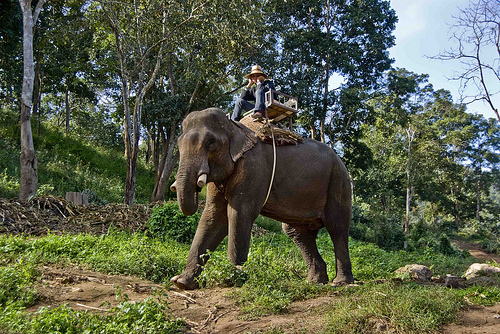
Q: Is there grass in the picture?
A: Yes, there is grass.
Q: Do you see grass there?
A: Yes, there is grass.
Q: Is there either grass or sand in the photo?
A: Yes, there is grass.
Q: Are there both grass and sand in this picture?
A: No, there is grass but no sand.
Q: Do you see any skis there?
A: No, there are no skis.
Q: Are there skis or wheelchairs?
A: No, there are no skis or wheelchairs.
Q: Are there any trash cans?
A: No, there are no trash cans.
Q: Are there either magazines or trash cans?
A: No, there are no trash cans or magazines.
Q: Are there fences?
A: No, there are no fences.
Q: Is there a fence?
A: No, there are no fences.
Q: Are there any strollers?
A: No, there are no strollers.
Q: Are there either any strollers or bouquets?
A: No, there are no strollers or bouquets.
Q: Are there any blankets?
A: Yes, there is a blanket.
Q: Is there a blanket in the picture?
A: Yes, there is a blanket.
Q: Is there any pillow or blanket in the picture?
A: Yes, there is a blanket.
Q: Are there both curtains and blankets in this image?
A: No, there is a blanket but no curtains.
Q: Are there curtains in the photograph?
A: No, there are no curtains.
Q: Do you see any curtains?
A: No, there are no curtains.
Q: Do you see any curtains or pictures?
A: No, there are no curtains or pictures.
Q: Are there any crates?
A: No, there are no crates.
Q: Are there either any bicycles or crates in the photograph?
A: No, there are no crates or bicycles.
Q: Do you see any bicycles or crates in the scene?
A: No, there are no crates or bicycles.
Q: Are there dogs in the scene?
A: No, there are no dogs.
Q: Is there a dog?
A: No, there are no dogs.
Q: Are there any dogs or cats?
A: No, there are no dogs or cats.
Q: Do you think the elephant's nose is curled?
A: Yes, the nose is curled.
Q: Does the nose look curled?
A: Yes, the nose is curled.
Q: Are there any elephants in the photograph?
A: Yes, there is an elephant.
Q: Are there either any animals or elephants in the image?
A: Yes, there is an elephant.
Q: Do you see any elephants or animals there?
A: Yes, there is an elephant.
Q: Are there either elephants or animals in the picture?
A: Yes, there is an elephant.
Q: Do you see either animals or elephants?
A: Yes, there is an elephant.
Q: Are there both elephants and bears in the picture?
A: No, there is an elephant but no bears.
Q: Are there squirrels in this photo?
A: No, there are no squirrels.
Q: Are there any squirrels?
A: No, there are no squirrels.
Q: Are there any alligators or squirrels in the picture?
A: No, there are no squirrels or alligators.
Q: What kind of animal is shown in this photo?
A: The animal is an elephant.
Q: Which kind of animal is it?
A: The animal is an elephant.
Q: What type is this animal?
A: This is an elephant.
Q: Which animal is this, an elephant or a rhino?
A: This is an elephant.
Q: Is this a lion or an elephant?
A: This is an elephant.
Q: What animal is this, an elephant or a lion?
A: This is an elephant.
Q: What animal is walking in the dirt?
A: The elephant is walking in the dirt.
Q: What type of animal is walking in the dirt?
A: The animal is an elephant.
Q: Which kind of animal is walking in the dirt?
A: The animal is an elephant.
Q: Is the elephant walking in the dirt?
A: Yes, the elephant is walking in the dirt.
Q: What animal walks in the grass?
A: The elephant walks in the grass.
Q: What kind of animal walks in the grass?
A: The animal is an elephant.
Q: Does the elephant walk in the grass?
A: Yes, the elephant walks in the grass.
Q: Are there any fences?
A: No, there are no fences.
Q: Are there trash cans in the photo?
A: No, there are no trash cans.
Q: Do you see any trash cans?
A: No, there are no trash cans.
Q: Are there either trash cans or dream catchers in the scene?
A: No, there are no trash cans or dream catchers.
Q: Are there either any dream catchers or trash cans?
A: No, there are no trash cans or dream catchers.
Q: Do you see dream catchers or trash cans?
A: No, there are no trash cans or dream catchers.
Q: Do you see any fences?
A: No, there are no fences.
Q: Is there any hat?
A: Yes, there is a hat.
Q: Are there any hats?
A: Yes, there is a hat.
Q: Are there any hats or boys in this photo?
A: Yes, there is a hat.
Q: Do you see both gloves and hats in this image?
A: No, there is a hat but no gloves.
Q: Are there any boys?
A: No, there are no boys.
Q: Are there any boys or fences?
A: No, there are no boys or fences.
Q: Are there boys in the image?
A: No, there are no boys.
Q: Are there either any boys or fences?
A: No, there are no boys or fences.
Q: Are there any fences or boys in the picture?
A: No, there are no boys or fences.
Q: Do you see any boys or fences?
A: No, there are no boys or fences.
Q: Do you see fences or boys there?
A: No, there are no boys or fences.